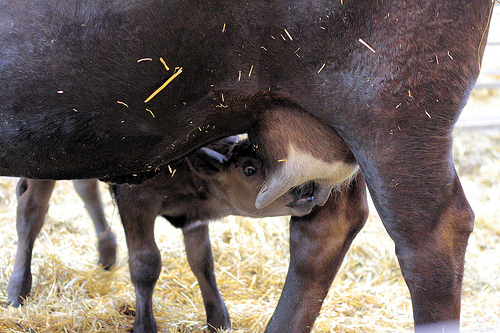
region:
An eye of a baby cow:
[236, 158, 263, 179]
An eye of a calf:
[239, 163, 264, 180]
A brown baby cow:
[4, 144, 292, 328]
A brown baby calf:
[5, 133, 318, 330]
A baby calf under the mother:
[4, 2, 484, 331]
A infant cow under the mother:
[1, 13, 491, 325]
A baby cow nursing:
[12, 33, 499, 327]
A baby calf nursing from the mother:
[2, 27, 497, 326]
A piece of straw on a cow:
[107, 89, 134, 122]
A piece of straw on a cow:
[354, 33, 383, 57]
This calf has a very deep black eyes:
[221, 151, 258, 188]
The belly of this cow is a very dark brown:
[67, 26, 93, 65]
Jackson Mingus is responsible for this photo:
[112, 25, 409, 332]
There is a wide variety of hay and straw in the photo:
[96, 38, 392, 304]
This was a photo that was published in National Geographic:
[130, 42, 379, 304]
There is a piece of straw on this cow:
[147, 50, 176, 93]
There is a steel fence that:
[491, 38, 498, 86]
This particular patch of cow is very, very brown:
[112, 16, 155, 41]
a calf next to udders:
[159, 71, 367, 254]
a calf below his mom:
[0, 70, 482, 327]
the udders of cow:
[245, 108, 361, 226]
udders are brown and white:
[254, 105, 359, 218]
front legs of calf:
[110, 205, 238, 328]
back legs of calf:
[6, 178, 120, 305]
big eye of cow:
[236, 156, 261, 182]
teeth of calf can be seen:
[287, 180, 319, 217]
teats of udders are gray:
[247, 173, 342, 221]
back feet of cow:
[271, 213, 471, 330]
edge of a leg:
[412, 218, 427, 250]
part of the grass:
[73, 293, 83, 313]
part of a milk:
[263, 180, 298, 197]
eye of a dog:
[248, 171, 260, 183]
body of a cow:
[146, 62, 165, 82]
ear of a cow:
[216, 157, 229, 164]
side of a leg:
[448, 248, 457, 264]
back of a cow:
[143, 130, 163, 154]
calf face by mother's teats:
[10, 62, 410, 307]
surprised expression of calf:
[181, 126, 318, 216]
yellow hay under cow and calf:
[2, 126, 492, 326]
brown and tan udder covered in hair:
[255, 111, 355, 216]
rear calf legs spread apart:
[5, 180, 115, 305]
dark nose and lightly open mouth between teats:
[252, 176, 324, 216]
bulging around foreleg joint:
[125, 220, 160, 316]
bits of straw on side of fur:
[60, 11, 450, 156]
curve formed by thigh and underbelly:
[125, 90, 380, 230]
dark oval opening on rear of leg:
[11, 166, 33, 199]